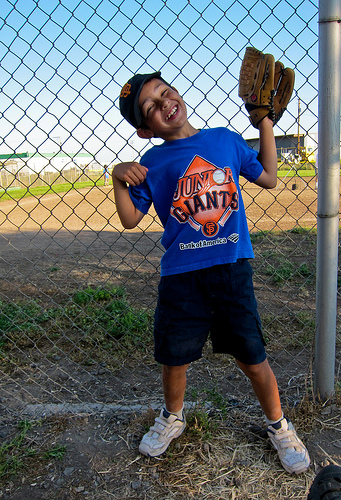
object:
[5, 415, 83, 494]
grass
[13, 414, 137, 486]
dirt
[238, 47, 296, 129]
baseball glove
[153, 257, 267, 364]
shorts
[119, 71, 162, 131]
hat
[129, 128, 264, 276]
blue shirt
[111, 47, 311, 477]
boy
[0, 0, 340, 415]
fence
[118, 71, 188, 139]
boy's head